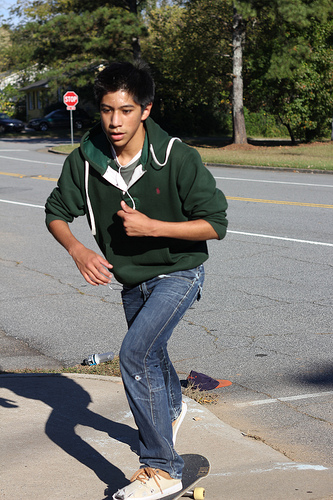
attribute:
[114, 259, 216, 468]
jeans — dark blue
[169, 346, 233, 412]
hat — blue, orange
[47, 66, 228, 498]
boy — teenager, skateboarding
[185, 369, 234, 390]
cap — blue, orange, baseball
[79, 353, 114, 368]
bottle — plastic, empty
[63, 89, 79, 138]
sign — distant, stop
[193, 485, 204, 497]
wheels — white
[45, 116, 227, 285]
hoodie — green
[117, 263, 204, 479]
jeans — blue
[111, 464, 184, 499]
shoe — tan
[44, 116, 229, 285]
jacket — dark green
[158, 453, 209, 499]
skateboard — black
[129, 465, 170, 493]
shoe laces — orange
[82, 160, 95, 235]
draw string — white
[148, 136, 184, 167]
draw string — white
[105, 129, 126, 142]
mouth — open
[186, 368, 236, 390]
hat — orange, blue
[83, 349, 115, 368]
bottle — empty, plastic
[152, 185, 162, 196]
logo — red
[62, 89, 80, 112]
stop sign — red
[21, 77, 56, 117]
house — yellow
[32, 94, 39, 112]
shutter — brown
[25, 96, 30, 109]
shutter — brown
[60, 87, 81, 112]
stop sign — red, octagon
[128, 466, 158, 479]
laces — orange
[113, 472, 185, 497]
shoe — yellow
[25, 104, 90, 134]
car — dark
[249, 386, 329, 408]
line — white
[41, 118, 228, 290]
sweater — green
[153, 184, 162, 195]
emblem — red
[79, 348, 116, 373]
bottle — empty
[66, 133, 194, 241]
hoodie —  skateboarder's , White string 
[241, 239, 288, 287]
road — middle , yellow line 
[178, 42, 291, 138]
greenery — picture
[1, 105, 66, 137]
cars — parked